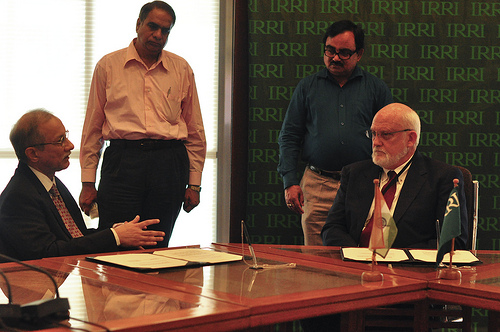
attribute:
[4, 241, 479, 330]
table — wood, glass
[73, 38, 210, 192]
shirt — pink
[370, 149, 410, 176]
beard — white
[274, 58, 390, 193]
shirt — blue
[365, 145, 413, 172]
beard — white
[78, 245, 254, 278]
booklet — open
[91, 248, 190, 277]
papers — white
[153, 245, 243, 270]
papers — white